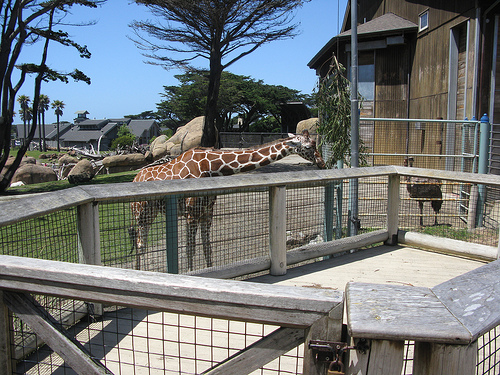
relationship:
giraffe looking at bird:
[125, 133, 328, 281] [392, 147, 456, 236]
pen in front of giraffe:
[11, 194, 471, 373] [129, 120, 348, 291]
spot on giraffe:
[252, 148, 263, 159] [133, 123, 323, 271]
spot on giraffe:
[169, 159, 184, 177] [133, 123, 323, 271]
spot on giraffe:
[240, 157, 260, 176] [133, 123, 323, 271]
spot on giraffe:
[201, 157, 211, 171] [133, 123, 323, 271]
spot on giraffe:
[154, 171, 175, 185] [133, 123, 323, 271]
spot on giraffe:
[154, 171, 175, 185] [121, 120, 320, 283]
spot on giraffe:
[223, 150, 236, 162] [121, 120, 320, 283]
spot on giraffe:
[185, 158, 202, 178] [121, 120, 320, 283]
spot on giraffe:
[252, 148, 266, 162] [121, 120, 320, 283]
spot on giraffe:
[260, 145, 279, 161] [125, 133, 328, 281]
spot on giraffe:
[198, 157, 217, 177] [125, 133, 328, 281]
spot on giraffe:
[170, 156, 184, 172] [125, 133, 328, 281]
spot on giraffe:
[149, 170, 161, 184] [125, 133, 328, 281]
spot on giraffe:
[185, 158, 202, 178] [133, 123, 323, 271]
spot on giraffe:
[149, 173, 157, 182] [133, 123, 323, 271]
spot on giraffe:
[219, 165, 232, 176] [133, 123, 323, 271]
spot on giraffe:
[273, 145, 283, 155] [133, 123, 323, 271]